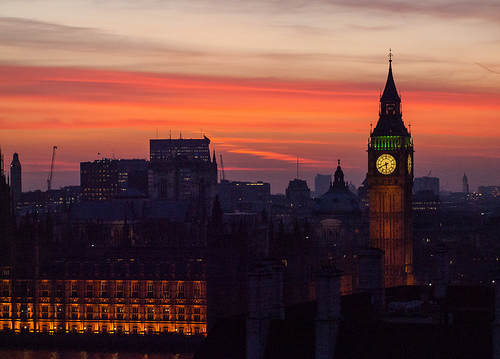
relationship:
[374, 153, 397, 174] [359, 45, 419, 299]
clock on building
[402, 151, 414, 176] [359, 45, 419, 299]
clock on building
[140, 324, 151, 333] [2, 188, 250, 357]
light on building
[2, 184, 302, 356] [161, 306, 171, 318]
building has light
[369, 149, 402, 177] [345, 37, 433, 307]
clock on tower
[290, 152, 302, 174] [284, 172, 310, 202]
pole on building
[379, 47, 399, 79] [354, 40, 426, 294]
rod on tower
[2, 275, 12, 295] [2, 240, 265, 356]
window in building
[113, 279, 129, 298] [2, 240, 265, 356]
window in building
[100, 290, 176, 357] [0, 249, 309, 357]
window in building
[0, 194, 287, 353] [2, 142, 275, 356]
wall on side of building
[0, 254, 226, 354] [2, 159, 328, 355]
wall on side of building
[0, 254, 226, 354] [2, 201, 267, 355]
wall on side of building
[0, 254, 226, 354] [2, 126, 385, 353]
wall on side of building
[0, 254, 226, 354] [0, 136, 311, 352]
wall on side of building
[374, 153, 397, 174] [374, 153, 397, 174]
clock has clock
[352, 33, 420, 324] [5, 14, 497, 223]
clock tower against sky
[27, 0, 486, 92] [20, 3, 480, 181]
clouds above sky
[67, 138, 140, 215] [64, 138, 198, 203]
lights in windows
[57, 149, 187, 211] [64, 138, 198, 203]
building has windows